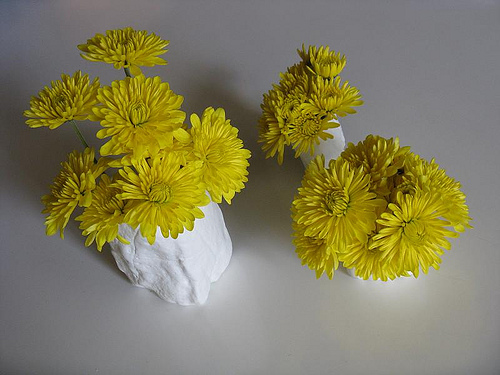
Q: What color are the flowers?
A: Yellow.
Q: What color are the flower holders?
A: White.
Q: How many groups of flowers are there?
A: Three.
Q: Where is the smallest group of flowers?
A: In the middle.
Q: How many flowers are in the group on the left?
A: Seven.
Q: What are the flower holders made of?
A: Rocks.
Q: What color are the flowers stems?
A: Green.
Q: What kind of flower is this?
A: Chrysanthemum.